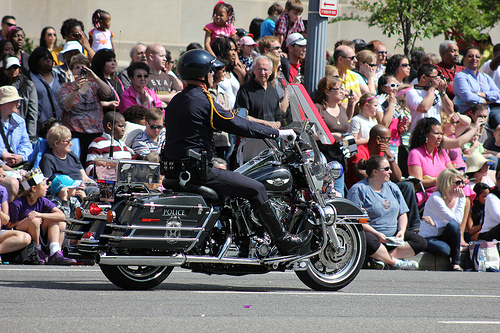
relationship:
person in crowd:
[410, 117, 463, 192] [2, 0, 497, 267]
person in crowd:
[405, 65, 442, 135] [2, 0, 497, 267]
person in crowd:
[455, 49, 487, 104] [2, 0, 497, 267]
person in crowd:
[345, 155, 428, 271] [2, 0, 497, 267]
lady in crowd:
[418, 168, 464, 271] [2, 0, 497, 267]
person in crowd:
[38, 121, 96, 194] [4, 41, 491, 252]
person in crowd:
[338, 152, 430, 274] [2, 0, 497, 267]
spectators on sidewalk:
[3, 3, 494, 269] [8, 32, 495, 272]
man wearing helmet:
[158, 48, 314, 257] [150, 36, 255, 103]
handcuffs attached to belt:
[172, 167, 193, 187] [154, 156, 212, 173]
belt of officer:
[154, 156, 212, 173] [155, 44, 316, 254]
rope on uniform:
[195, 83, 238, 132] [161, 87, 277, 206]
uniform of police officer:
[161, 87, 277, 206] [144, 42, 317, 259]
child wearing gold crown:
[10, 167, 77, 263] [18, 168, 46, 188]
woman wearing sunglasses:
[119, 59, 165, 121] [134, 69, 148, 80]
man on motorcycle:
[158, 48, 314, 257] [103, 144, 357, 298]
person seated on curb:
[345, 155, 428, 271] [412, 252, 447, 272]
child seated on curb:
[9, 165, 77, 265] [412, 248, 452, 269]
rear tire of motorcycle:
[98, 244, 179, 291] [62, 121, 367, 288]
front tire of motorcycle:
[296, 219, 364, 292] [51, 26, 400, 292]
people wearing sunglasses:
[378, 74, 413, 132] [399, 63, 408, 66]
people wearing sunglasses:
[385, 55, 411, 81] [378, 50, 385, 52]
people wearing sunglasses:
[356, 50, 379, 97] [346, 55, 357, 58]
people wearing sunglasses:
[366, 40, 388, 93] [346, 55, 357, 58]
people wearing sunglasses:
[328, 43, 366, 110] [399, 63, 408, 66]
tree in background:
[328, 1, 498, 59] [284, 9, 483, 79]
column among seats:
[303, 0, 328, 102] [297, 73, 433, 169]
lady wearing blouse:
[418, 163, 475, 270] [420, 192, 470, 238]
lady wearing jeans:
[418, 163, 475, 270] [430, 224, 466, 262]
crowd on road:
[4, 15, 481, 252] [1, 264, 499, 331]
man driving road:
[158, 48, 314, 257] [89, 245, 452, 318]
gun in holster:
[187, 148, 209, 176] [201, 143, 214, 189]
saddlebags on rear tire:
[58, 181, 213, 276] [98, 244, 180, 291]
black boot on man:
[250, 195, 315, 256] [160, 45, 313, 253]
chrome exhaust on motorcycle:
[87, 252, 187, 269] [62, 121, 367, 288]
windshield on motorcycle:
[255, 72, 315, 117] [55, 78, 395, 293]